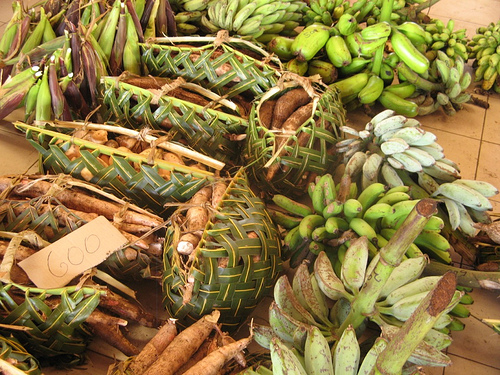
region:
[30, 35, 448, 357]
this is at a market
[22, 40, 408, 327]
these are fruits and vegetables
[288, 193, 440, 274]
these are bananas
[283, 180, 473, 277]
the bananas are green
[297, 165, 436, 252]
the bananas are ripe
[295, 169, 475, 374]
these fruits are in bunches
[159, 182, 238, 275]
this food is brown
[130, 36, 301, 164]
the food is stored in baskets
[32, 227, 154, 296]
the sign says GOO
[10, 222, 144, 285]
this is a cardboard sign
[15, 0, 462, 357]
fruit and root vegetables on the ground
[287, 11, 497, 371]
mini green bananas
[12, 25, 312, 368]
root vegetables in bags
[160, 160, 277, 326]
bags made from leaves of a plant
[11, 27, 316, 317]
root vegetables in 7 bags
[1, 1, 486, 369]
fruit resting on a tiled floor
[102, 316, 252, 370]
yucca root or sweet potatoes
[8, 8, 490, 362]
Many fruits and vegetables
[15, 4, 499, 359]
The produce is for sale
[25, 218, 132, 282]
The sign is made of cardboard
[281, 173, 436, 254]
All of the bananas are green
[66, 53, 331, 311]
A bunch of handmade baskets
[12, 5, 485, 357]
The produce is on the ground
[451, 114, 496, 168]
The tile is square shaped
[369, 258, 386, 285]
A backwards number 3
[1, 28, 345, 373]
yellow roots wrapped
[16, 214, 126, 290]
a sign for six dollars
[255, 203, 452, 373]
dusty green peppers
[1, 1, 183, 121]
purple beans on left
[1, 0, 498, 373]
a table of vegatables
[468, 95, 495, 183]
the lines on table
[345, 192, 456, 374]
the stem on peppers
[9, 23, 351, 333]
the woven baskets with roots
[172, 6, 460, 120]
the bananas in the back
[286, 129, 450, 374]
the bananas in the front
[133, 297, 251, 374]
the roots on the ground in the front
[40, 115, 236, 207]
the roots in the middle basket with the bamboo handles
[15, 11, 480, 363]
the tropical scene from harvested roots and bananas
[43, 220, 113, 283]
a sign that says 600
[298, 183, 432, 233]
lime green small bananas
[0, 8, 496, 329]
a whole lot of green fruits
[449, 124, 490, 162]
cream color dirty tile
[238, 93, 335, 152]
brown vegetables in leave basket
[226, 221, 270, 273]
green leaves weaved together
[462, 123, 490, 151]
the tile is dirty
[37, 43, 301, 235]
five leave baskets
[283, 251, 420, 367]
dirty green stemmed vegetables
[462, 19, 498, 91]
bright green small bananas